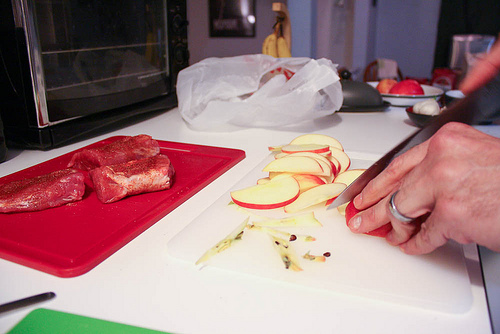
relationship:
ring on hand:
[388, 190, 418, 223] [351, 119, 498, 253]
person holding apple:
[339, 117, 497, 270] [226, 129, 428, 269]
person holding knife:
[348, 118, 498, 258] [325, 67, 498, 210]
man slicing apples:
[345, 30, 498, 269] [196, 130, 430, 277]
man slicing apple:
[348, 41, 500, 257] [228, 172, 301, 210]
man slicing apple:
[348, 41, 500, 257] [282, 179, 347, 215]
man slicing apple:
[348, 41, 500, 257] [260, 154, 325, 174]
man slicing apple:
[348, 41, 500, 257] [264, 142, 329, 154]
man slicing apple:
[348, 41, 500, 257] [342, 199, 392, 235]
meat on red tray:
[85, 137, 173, 190] [1, 132, 248, 278]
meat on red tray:
[2, 170, 83, 208] [1, 132, 248, 278]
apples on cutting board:
[226, 127, 373, 221] [163, 141, 476, 316]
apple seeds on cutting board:
[190, 215, 334, 279] [163, 141, 476, 316]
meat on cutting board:
[0, 130, 177, 216] [1, 135, 246, 277]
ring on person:
[388, 190, 418, 223] [338, 33, 498, 285]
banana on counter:
[278, 33, 289, 58] [146, 112, 411, 140]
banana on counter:
[264, 32, 279, 62] [146, 112, 411, 140]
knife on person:
[325, 67, 498, 210] [348, 36, 499, 255]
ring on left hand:
[381, 175, 438, 251] [356, 121, 483, 258]